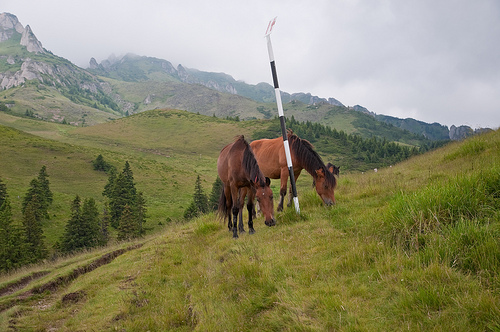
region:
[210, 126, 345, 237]
two horses eating grass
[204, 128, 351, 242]
two horses nears a pole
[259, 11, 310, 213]
pole is white and black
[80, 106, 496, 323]
two horses on a hill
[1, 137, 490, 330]
hill is covered with grass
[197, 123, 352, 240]
horses are color brown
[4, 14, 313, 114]
rocky mountains on the background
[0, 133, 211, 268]
pines trees are green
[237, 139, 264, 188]
mane of horse is dark brown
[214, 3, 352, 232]
a pole in middle of two horses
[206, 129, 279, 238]
A dark brown horse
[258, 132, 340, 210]
A red colored horse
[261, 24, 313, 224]
A black and white pole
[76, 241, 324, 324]
A green grassy hill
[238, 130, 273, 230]
Black horses mane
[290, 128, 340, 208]
A red horse with black mane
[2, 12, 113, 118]
A rocky mountain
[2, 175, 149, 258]
Green pine trees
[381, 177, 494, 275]
Tall green grass on hill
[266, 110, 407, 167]
A hill of pine trees on mountain behind horses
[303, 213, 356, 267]
part of a grass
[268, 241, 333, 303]
part of a ground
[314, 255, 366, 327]
aprt of a fiedl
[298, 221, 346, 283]
part of a ground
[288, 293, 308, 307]
part of a ground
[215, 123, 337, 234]
two horses standing together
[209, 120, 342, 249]
two horses standing on a hill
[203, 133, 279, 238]
brown horse bent over on hill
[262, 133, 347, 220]
brown horse grazing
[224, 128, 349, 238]
two horses grazing on field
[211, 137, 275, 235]
brown horse looking up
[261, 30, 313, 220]
black and white pole between horses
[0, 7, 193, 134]
large mountain range in background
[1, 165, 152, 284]
trees and grass all over the hill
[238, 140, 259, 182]
long black mane of horse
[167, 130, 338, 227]
the horses are brown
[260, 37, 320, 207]
the pole is black and white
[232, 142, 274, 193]
horse's mane hair is black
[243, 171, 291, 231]
horse is eating grass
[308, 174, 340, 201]
horse's eye is black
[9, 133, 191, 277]
pine trees on the grass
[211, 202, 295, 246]
the horse's hooves are black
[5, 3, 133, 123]
rocky mountain in distance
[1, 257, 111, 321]
patches are in the grass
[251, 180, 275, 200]
white spot on horse